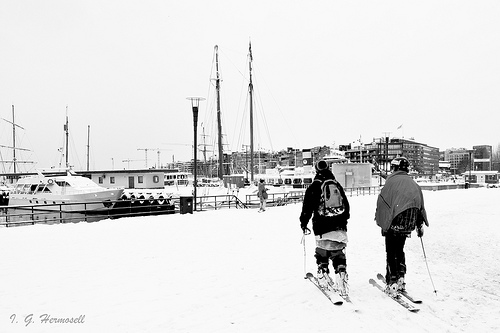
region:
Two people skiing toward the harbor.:
[292, 137, 442, 323]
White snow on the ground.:
[77, 218, 233, 291]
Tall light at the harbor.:
[182, 88, 207, 207]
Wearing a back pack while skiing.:
[313, 178, 358, 218]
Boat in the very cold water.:
[9, 175, 131, 217]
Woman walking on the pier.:
[248, 176, 275, 212]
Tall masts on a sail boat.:
[242, 28, 259, 185]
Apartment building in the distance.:
[341, 137, 445, 169]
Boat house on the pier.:
[83, 171, 169, 190]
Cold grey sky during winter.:
[307, 21, 455, 90]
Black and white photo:
[27, 10, 489, 319]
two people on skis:
[292, 143, 457, 322]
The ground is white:
[25, 222, 492, 330]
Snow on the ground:
[7, 188, 494, 323]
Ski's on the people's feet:
[294, 259, 441, 320]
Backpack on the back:
[302, 163, 354, 220]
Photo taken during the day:
[0, 19, 487, 322]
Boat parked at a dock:
[0, 163, 137, 218]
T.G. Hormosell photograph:
[0, 310, 100, 331]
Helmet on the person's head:
[385, 155, 416, 182]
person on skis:
[300, 154, 355, 326]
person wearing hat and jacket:
[365, 144, 432, 331]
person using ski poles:
[281, 154, 358, 305]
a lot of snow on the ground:
[61, 193, 496, 317]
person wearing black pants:
[366, 148, 428, 310]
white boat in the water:
[18, 159, 98, 216]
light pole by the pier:
[181, 86, 223, 218]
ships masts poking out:
[209, 28, 280, 246]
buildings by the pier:
[361, 130, 435, 198]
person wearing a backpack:
[307, 172, 358, 234]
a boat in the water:
[6, 167, 121, 219]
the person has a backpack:
[313, 175, 347, 225]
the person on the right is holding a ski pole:
[367, 156, 442, 315]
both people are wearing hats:
[297, 145, 438, 317]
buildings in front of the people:
[168, 135, 499, 190]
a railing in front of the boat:
[0, 193, 260, 233]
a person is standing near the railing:
[197, 175, 304, 215]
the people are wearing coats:
[293, 155, 445, 317]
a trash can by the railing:
[126, 194, 244, 215]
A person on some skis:
[297, 156, 351, 296]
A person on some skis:
[375, 154, 427, 294]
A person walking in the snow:
[254, 173, 270, 210]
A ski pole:
[300, 225, 312, 277]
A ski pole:
[415, 230, 438, 295]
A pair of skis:
[306, 271, 361, 312]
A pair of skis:
[369, 268, 421, 313]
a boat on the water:
[7, 169, 124, 209]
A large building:
[342, 132, 440, 175]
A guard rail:
[0, 193, 233, 225]